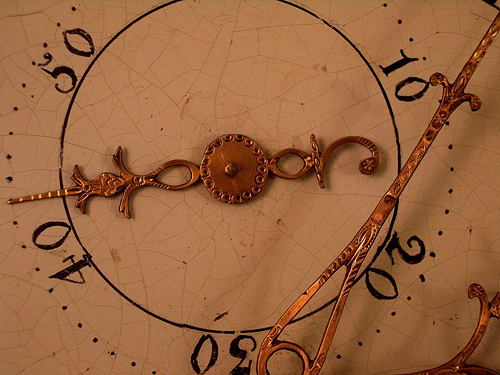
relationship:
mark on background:
[109, 247, 123, 262] [0, 2, 498, 373]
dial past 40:
[9, 130, 382, 216] [31, 220, 91, 287]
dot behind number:
[22, 82, 26, 86] [37, 50, 77, 95]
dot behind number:
[422, 55, 427, 61] [379, 50, 419, 77]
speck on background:
[322, 64, 327, 73] [0, 2, 498, 373]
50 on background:
[38, 28, 96, 93] [0, 2, 498, 373]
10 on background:
[379, 49, 431, 101] [0, 2, 498, 373]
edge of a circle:
[57, 145, 67, 171] [57, 4, 403, 335]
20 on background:
[361, 232, 424, 300] [0, 2, 498, 373]